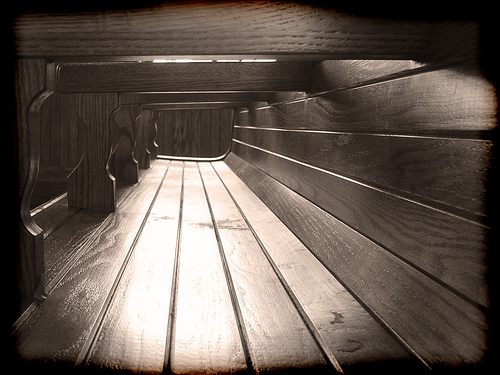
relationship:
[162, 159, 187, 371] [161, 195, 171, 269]
crack between wood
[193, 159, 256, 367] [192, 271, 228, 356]
crack between wood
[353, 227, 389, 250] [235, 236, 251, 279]
crevice between wood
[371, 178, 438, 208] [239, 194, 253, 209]
crevice between wood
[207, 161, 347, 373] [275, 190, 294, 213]
crack between wood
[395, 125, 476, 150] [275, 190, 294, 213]
crevice between wood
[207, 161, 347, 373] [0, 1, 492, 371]
crack in wood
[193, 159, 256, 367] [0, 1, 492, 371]
crack in wood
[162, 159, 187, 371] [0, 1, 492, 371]
crack in wood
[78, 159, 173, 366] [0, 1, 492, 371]
crack in wood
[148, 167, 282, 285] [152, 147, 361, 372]
carvings in wood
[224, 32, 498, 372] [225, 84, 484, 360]
planks forming backsit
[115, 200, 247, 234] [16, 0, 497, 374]
mark on bench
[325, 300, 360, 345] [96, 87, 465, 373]
mark on bench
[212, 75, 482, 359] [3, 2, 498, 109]
planks part of seat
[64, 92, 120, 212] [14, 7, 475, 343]
plank part of seat divider